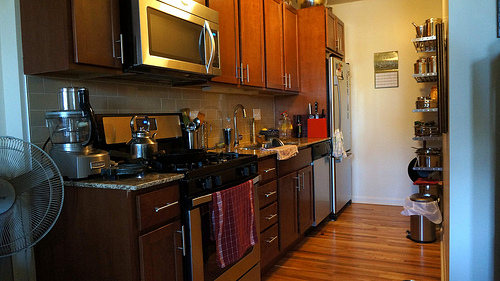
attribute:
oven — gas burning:
[96, 112, 273, 279]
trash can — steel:
[407, 194, 440, 244]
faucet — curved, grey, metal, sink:
[226, 101, 277, 151]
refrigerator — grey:
[326, 55, 354, 220]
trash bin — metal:
[405, 190, 438, 241]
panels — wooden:
[311, 219, 415, 266]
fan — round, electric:
[0, 133, 67, 263]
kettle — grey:
[104, 97, 174, 175]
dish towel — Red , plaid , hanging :
[207, 187, 259, 262]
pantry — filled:
[406, 14, 447, 196]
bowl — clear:
[44, 117, 94, 143]